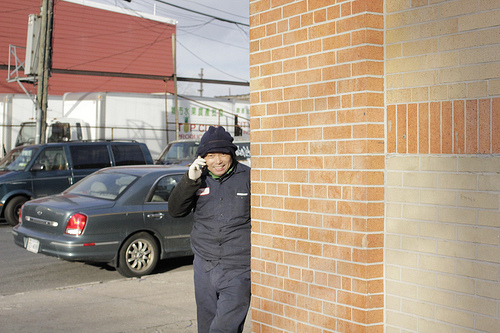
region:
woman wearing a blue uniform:
[170, 140, 259, 330]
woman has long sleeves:
[148, 155, 233, 218]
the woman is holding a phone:
[160, 120, 252, 228]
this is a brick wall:
[255, 47, 382, 307]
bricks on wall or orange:
[271, 34, 368, 287]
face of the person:
[189, 120, 251, 183]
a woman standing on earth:
[161, 126, 271, 331]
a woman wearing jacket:
[180, 170, 245, 227]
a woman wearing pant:
[181, 266, 268, 330]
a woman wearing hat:
[177, 117, 255, 174]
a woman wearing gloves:
[164, 140, 221, 205]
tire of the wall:
[117, 228, 179, 295]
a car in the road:
[16, 155, 198, 304]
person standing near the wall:
[158, 120, 263, 332]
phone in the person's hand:
[191, 150, 208, 175]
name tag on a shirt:
[193, 183, 215, 196]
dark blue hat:
[189, 120, 240, 160]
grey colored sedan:
[11, 157, 240, 281]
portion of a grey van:
[160, 131, 259, 184]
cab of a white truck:
[8, 110, 93, 166]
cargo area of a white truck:
[63, 87, 255, 170]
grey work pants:
[188, 248, 255, 331]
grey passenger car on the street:
[9, 155, 261, 282]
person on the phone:
[161, 115, 269, 332]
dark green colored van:
[3, 130, 164, 238]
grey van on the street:
[156, 130, 257, 181]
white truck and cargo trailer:
[15, 82, 265, 178]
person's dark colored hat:
[193, 123, 248, 163]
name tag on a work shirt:
[193, 185, 214, 198]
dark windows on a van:
[71, 146, 148, 172]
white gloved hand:
[185, 155, 209, 185]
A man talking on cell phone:
[168, 126, 249, 331]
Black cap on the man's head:
[195, 126, 235, 155]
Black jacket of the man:
[168, 163, 249, 268]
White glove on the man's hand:
[187, 155, 206, 177]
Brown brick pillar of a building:
[249, 1, 384, 331]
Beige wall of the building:
[384, 2, 499, 330]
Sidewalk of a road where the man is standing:
[0, 266, 195, 331]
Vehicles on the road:
[0, 134, 250, 277]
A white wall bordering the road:
[0, 91, 250, 166]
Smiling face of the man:
[204, 152, 231, 175]